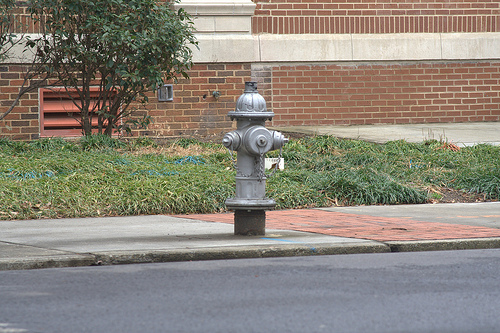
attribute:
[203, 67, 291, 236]
hydrant — silver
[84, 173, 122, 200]
grass — green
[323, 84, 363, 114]
wall — brick